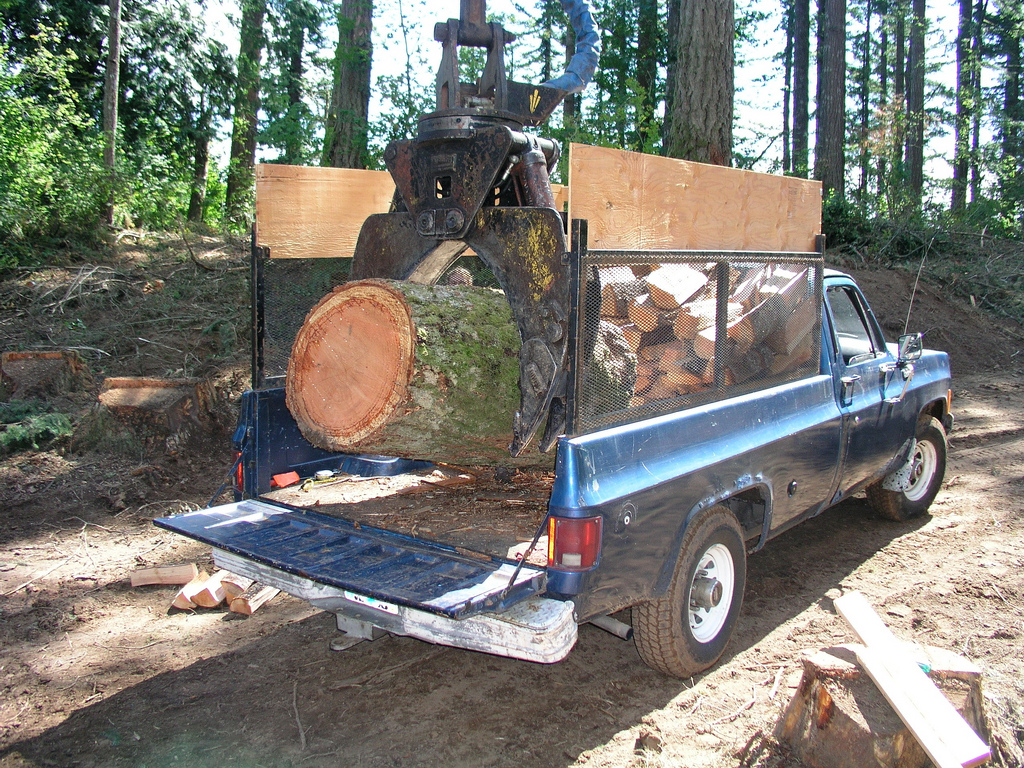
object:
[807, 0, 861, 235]
tree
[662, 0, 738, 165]
tree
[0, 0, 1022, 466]
woods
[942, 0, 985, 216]
tree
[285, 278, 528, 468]
tree trunk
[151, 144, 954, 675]
truck